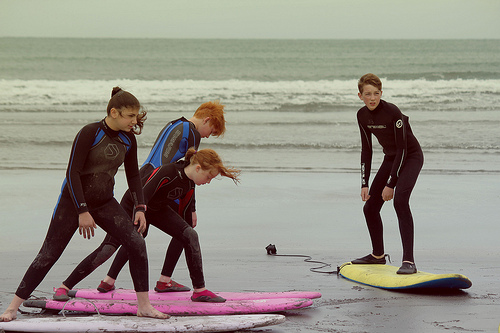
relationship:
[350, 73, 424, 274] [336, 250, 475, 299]
children standing surfboard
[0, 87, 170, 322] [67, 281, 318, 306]
girl standing surfboard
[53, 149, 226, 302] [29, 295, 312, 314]
girl standing surfboard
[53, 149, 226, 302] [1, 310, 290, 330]
girl standing surfboard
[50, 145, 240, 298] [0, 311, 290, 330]
girl on white surfboard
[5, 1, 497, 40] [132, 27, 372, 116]
sky above ocean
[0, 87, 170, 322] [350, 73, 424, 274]
girl learning children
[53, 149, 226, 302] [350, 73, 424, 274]
girl learning children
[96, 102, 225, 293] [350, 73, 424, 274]
kids learning children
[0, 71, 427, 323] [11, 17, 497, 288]
they learning at beach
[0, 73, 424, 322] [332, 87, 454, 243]
they wearing wetsuits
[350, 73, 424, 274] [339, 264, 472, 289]
children standing on board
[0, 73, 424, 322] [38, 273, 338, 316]
they standing on boards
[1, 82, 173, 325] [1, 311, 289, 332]
girl on surfboard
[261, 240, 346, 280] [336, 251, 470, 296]
ankle rope attached to back of board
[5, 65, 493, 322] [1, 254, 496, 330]
children standing on surfboards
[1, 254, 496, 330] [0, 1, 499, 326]
surfboards on beach